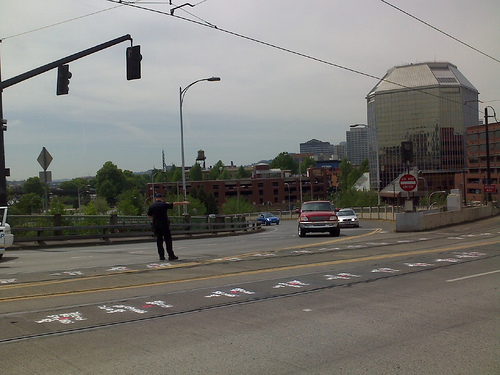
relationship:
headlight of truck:
[300, 214, 309, 225] [297, 197, 342, 239]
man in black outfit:
[146, 191, 178, 262] [146, 199, 178, 256]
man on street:
[146, 191, 188, 262] [135, 259, 255, 323]